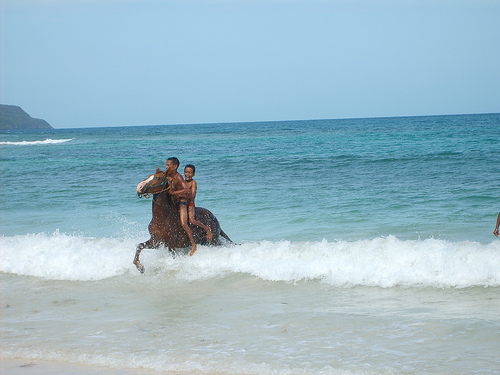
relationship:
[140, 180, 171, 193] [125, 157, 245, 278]
bridle of horse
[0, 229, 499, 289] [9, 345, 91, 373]
surf washing up on sand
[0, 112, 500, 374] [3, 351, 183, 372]
ocean along sand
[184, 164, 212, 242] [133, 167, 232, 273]
boy riding brown horse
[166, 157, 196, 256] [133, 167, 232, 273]
boy riding brown horse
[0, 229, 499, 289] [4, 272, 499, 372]
surf crashing on beach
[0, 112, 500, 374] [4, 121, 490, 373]
ocean on beach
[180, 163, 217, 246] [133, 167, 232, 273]
boy riding brown horse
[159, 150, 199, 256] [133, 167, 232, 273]
boy riding brown horse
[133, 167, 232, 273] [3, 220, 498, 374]
brown horse on beach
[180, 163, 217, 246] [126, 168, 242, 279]
boy riding horse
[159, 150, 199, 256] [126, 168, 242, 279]
boy riding horse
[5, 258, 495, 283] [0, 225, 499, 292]
line of surf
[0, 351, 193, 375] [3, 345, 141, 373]
sand of sand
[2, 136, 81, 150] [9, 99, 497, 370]
foam of wave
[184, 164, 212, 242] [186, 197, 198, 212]
boy in suit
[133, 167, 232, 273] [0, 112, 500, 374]
brown horse through ocean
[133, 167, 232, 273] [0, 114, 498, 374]
brown horse running through ocean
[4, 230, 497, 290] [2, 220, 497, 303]
foam on wave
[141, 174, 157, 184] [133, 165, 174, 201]
spot on head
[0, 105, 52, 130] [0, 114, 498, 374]
cliff on side of ocean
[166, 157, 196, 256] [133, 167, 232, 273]
boy on back of brown horse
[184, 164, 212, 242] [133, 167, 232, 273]
boy on back of brown horse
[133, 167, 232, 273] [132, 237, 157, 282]
brown horse lifting up leg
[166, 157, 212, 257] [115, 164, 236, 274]
boys riding horse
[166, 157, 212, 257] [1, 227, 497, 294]
boys riding through waves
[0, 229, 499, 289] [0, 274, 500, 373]
surf crashing up on beach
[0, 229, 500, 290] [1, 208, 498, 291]
foam on waves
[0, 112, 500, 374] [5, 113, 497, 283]
ocean in ocean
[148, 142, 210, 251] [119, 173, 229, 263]
boys riding horse